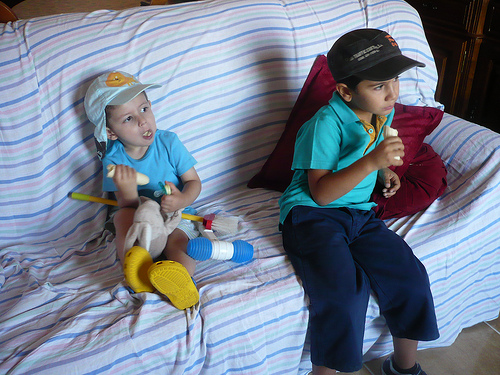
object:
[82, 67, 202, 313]
child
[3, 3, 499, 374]
couch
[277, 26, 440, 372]
child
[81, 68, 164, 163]
hat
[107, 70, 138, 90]
goldfish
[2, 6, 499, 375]
blanket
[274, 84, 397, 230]
shirt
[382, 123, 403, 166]
banana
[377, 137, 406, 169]
right hand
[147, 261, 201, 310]
shoe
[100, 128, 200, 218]
shirt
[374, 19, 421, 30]
stripe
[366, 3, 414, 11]
stripe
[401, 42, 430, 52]
stripe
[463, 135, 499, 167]
stripe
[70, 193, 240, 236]
toy broom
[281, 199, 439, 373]
pants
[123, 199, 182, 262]
toy rabbit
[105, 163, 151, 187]
banana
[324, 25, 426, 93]
hat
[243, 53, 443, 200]
pillow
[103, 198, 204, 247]
lap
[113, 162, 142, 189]
right hand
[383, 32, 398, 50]
logo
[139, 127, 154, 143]
mouth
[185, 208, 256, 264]
toy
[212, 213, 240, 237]
bristles